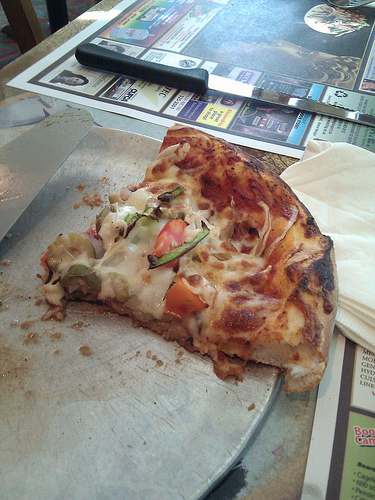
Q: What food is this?
A: Pizza.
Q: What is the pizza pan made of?
A: Metal.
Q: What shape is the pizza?
A: Triangle.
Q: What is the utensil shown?
A: Knife.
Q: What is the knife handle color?
A: Black.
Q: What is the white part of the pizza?
A: Melted cheese.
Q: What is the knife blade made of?
A: Metal.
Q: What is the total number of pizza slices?
A: 1.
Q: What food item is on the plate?
A: Pizza.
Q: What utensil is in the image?
A: Knife.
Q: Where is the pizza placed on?
A: Table.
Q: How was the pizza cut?
A: Sliced.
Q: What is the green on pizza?
A: Bell peppers.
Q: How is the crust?
A: Thick.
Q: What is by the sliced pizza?
A: Napkins.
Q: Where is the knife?
A: Table.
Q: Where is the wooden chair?
A: At table.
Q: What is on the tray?
A: A pizza.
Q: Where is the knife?
A: On the table.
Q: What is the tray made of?
A: Metal.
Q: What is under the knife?
A: An ad.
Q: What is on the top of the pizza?
A: Cheese, tomato and pepper.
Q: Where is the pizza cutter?
A: On the tray.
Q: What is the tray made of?
A: Metal.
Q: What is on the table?
A: Ad, knife and tray.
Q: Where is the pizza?
A: On the tray.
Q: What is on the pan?
A: Pizza.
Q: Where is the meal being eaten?
A: Restaurant.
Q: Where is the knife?
A: On a placemat.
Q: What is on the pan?
A: Pizza.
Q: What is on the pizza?
A: Cheese, tomatoes, peppers.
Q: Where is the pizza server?
A: Next to the pizza.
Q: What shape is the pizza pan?
A: Round.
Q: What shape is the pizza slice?
A: Triangular.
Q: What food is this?
A: Pizza.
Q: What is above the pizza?
A: Knife.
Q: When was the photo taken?
A: Daytime.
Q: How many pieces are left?
A: One.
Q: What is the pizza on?
A: Pan.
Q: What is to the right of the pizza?
A: Napkins.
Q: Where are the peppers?
A: On pizza.